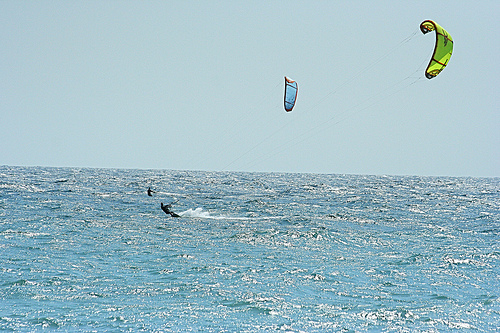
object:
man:
[160, 202, 180, 217]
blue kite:
[283, 76, 299, 112]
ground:
[393, 207, 422, 232]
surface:
[385, 187, 482, 281]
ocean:
[0, 166, 499, 333]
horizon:
[0, 164, 499, 184]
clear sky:
[0, 0, 499, 178]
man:
[147, 187, 156, 196]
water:
[38, 210, 500, 333]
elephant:
[414, 13, 463, 83]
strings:
[408, 29, 423, 45]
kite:
[411, 10, 456, 88]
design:
[440, 28, 448, 46]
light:
[185, 256, 282, 310]